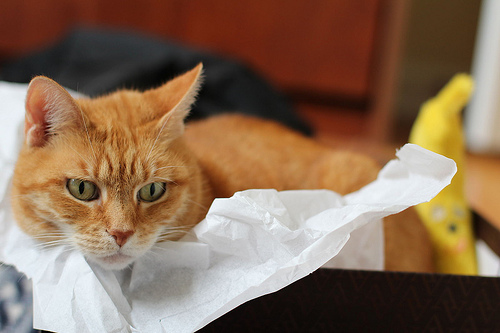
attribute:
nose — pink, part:
[95, 220, 153, 265]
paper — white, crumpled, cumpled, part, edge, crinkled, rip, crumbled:
[325, 136, 441, 244]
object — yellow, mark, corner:
[413, 64, 493, 181]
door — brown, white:
[391, 33, 469, 99]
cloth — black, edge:
[80, 16, 149, 72]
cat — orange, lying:
[3, 30, 251, 275]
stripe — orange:
[87, 101, 170, 201]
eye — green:
[58, 165, 119, 222]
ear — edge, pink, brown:
[9, 62, 103, 170]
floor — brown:
[359, 134, 384, 149]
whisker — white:
[12, 214, 83, 283]